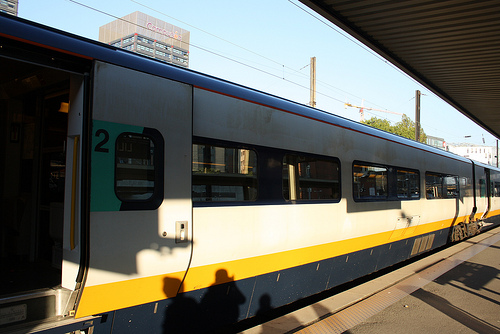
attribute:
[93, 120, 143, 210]
sign — green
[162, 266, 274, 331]
shadow — of people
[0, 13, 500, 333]
train — black, yellow, white, visible from side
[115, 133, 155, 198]
window — clear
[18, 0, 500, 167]
sky — baby blue, clear, cloudless, blue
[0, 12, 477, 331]
train car — open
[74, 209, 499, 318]
stripe — yellow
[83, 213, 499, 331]
stripe — blue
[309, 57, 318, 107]
pole — wooden, telephone pole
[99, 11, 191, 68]
building — tall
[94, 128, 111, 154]
number — 2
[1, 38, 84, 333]
train door — open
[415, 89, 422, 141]
pole — wooden